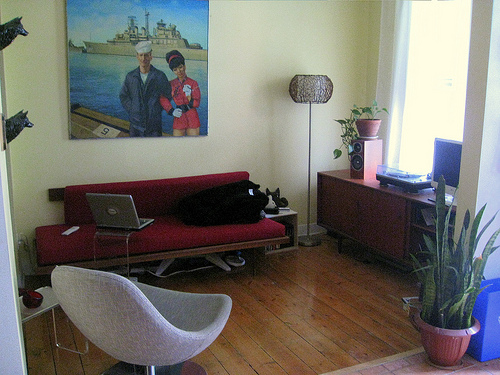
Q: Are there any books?
A: No, there are no books.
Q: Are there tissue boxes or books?
A: No, there are no books or tissue boxes.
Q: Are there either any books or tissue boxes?
A: No, there are no books or tissue boxes.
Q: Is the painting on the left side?
A: Yes, the painting is on the left of the image.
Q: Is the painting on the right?
A: No, the painting is on the left of the image.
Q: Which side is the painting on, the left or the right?
A: The painting is on the left of the image.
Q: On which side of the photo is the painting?
A: The painting is on the left of the image.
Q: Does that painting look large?
A: Yes, the painting is large.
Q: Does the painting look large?
A: Yes, the painting is large.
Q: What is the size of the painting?
A: The painting is large.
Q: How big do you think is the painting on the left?
A: The painting is large.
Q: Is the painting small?
A: No, the painting is large.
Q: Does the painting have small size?
A: No, the painting is large.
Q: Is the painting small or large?
A: The painting is large.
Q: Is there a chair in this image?
A: Yes, there is a chair.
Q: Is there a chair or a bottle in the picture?
A: Yes, there is a chair.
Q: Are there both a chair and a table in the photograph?
A: Yes, there are both a chair and a table.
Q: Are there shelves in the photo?
A: No, there are no shelves.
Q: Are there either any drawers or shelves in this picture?
A: No, there are no shelves or drawers.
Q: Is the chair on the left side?
A: Yes, the chair is on the left of the image.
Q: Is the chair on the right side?
A: No, the chair is on the left of the image.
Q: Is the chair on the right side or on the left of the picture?
A: The chair is on the left of the image.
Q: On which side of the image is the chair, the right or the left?
A: The chair is on the left of the image.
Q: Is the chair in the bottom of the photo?
A: Yes, the chair is in the bottom of the image.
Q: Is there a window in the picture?
A: Yes, there is a window.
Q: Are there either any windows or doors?
A: Yes, there is a window.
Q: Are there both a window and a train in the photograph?
A: No, there is a window but no trains.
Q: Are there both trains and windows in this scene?
A: No, there is a window but no trains.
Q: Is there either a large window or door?
A: Yes, there is a large window.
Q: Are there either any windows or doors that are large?
A: Yes, the window is large.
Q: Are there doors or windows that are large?
A: Yes, the window is large.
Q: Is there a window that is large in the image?
A: Yes, there is a large window.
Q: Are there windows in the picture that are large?
A: Yes, there is a window that is large.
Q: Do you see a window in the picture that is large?
A: Yes, there is a window that is large.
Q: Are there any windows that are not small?
A: Yes, there is a large window.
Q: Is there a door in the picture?
A: No, there are no doors.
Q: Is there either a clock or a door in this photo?
A: No, there are no doors or clocks.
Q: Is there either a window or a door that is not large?
A: No, there is a window but it is large.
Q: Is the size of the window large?
A: Yes, the window is large.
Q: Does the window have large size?
A: Yes, the window is large.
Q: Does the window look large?
A: Yes, the window is large.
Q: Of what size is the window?
A: The window is large.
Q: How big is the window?
A: The window is large.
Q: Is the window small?
A: No, the window is large.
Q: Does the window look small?
A: No, the window is large.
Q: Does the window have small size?
A: No, the window is large.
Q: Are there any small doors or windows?
A: No, there is a window but it is large.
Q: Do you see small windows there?
A: No, there is a window but it is large.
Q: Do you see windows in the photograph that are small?
A: No, there is a window but it is large.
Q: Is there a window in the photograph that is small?
A: No, there is a window but it is large.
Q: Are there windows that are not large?
A: No, there is a window but it is large.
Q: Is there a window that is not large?
A: No, there is a window but it is large.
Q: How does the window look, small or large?
A: The window is large.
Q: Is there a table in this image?
A: Yes, there is a table.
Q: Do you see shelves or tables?
A: Yes, there is a table.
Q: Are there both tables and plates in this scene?
A: No, there is a table but no plates.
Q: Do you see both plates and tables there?
A: No, there is a table but no plates.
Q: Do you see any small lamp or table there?
A: Yes, there is a small table.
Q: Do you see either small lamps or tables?
A: Yes, there is a small table.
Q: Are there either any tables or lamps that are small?
A: Yes, the table is small.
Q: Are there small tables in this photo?
A: Yes, there is a small table.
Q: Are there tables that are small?
A: Yes, there is a table that is small.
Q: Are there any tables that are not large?
A: Yes, there is a small table.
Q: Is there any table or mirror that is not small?
A: No, there is a table but it is small.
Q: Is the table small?
A: Yes, the table is small.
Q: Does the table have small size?
A: Yes, the table is small.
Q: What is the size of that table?
A: The table is small.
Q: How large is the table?
A: The table is small.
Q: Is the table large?
A: No, the table is small.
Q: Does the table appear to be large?
A: No, the table is small.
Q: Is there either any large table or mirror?
A: No, there is a table but it is small.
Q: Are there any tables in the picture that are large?
A: No, there is a table but it is small.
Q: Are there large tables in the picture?
A: No, there is a table but it is small.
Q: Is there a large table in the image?
A: No, there is a table but it is small.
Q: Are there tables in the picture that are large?
A: No, there is a table but it is small.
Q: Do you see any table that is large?
A: No, there is a table but it is small.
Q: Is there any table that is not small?
A: No, there is a table but it is small.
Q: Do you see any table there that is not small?
A: No, there is a table but it is small.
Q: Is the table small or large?
A: The table is small.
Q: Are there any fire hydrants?
A: No, there are no fire hydrants.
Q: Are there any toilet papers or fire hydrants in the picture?
A: No, there are no fire hydrants or toilet papers.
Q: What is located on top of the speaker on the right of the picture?
A: The plant is on top of the speaker.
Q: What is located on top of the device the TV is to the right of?
A: The plant is on top of the speaker.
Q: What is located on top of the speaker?
A: The plant is on top of the speaker.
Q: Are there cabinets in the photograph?
A: Yes, there is a cabinet.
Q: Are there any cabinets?
A: Yes, there is a cabinet.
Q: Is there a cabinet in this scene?
A: Yes, there is a cabinet.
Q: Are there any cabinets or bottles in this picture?
A: Yes, there is a cabinet.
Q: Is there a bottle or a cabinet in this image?
A: Yes, there is a cabinet.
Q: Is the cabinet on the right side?
A: Yes, the cabinet is on the right of the image.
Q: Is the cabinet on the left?
A: No, the cabinet is on the right of the image.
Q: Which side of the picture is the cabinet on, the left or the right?
A: The cabinet is on the right of the image.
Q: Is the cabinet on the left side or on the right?
A: The cabinet is on the right of the image.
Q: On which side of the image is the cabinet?
A: The cabinet is on the right of the image.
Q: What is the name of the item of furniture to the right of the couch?
A: The piece of furniture is a cabinet.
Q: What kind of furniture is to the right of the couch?
A: The piece of furniture is a cabinet.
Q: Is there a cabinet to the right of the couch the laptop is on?
A: Yes, there is a cabinet to the right of the couch.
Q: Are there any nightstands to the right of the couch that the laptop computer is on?
A: No, there is a cabinet to the right of the couch.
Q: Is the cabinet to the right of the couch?
A: Yes, the cabinet is to the right of the couch.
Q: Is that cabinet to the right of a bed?
A: No, the cabinet is to the right of the couch.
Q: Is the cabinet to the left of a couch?
A: No, the cabinet is to the right of a couch.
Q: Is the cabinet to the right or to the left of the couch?
A: The cabinet is to the right of the couch.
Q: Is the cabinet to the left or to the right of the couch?
A: The cabinet is to the right of the couch.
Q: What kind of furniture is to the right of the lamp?
A: The piece of furniture is a cabinet.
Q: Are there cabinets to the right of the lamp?
A: Yes, there is a cabinet to the right of the lamp.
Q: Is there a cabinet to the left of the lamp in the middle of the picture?
A: No, the cabinet is to the right of the lamp.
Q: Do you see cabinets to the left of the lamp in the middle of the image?
A: No, the cabinet is to the right of the lamp.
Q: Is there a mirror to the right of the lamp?
A: No, there is a cabinet to the right of the lamp.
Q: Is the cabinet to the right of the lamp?
A: Yes, the cabinet is to the right of the lamp.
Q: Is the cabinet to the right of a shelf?
A: No, the cabinet is to the right of the lamp.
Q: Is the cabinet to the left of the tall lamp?
A: No, the cabinet is to the right of the lamp.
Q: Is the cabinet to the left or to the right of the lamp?
A: The cabinet is to the right of the lamp.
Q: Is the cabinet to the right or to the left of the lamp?
A: The cabinet is to the right of the lamp.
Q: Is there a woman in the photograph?
A: Yes, there is a woman.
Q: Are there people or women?
A: Yes, there is a woman.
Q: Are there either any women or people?
A: Yes, there is a woman.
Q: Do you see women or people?
A: Yes, there is a woman.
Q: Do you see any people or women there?
A: Yes, there is a woman.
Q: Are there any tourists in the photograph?
A: No, there are no tourists.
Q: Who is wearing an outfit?
A: The woman is wearing an outfit.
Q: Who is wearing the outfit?
A: The woman is wearing an outfit.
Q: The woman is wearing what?
A: The woman is wearing an outfit.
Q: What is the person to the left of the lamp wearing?
A: The woman is wearing an outfit.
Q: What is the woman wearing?
A: The woman is wearing an outfit.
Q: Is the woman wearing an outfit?
A: Yes, the woman is wearing an outfit.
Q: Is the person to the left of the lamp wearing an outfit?
A: Yes, the woman is wearing an outfit.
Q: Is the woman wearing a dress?
A: No, the woman is wearing an outfit.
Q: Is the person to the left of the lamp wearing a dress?
A: No, the woman is wearing an outfit.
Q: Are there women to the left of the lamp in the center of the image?
A: Yes, there is a woman to the left of the lamp.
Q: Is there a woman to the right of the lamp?
A: No, the woman is to the left of the lamp.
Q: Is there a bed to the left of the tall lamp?
A: No, there is a woman to the left of the lamp.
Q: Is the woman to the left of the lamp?
A: Yes, the woman is to the left of the lamp.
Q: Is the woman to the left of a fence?
A: No, the woman is to the left of the lamp.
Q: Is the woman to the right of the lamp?
A: No, the woman is to the left of the lamp.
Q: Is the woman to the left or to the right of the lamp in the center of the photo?
A: The woman is to the left of the lamp.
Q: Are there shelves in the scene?
A: No, there are no shelves.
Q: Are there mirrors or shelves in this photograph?
A: No, there are no shelves or mirrors.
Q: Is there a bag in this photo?
A: No, there are no bags.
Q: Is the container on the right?
A: Yes, the container is on the right of the image.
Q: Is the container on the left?
A: No, the container is on the right of the image.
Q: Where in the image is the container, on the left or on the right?
A: The container is on the right of the image.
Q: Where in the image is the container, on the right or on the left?
A: The container is on the right of the image.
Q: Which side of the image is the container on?
A: The container is on the right of the image.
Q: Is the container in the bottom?
A: Yes, the container is in the bottom of the image.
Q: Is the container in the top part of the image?
A: No, the container is in the bottom of the image.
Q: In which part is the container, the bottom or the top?
A: The container is in the bottom of the image.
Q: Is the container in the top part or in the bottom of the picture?
A: The container is in the bottom of the image.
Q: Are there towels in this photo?
A: No, there are no towels.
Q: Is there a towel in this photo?
A: No, there are no towels.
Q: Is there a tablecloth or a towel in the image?
A: No, there are no towels or tablecloths.